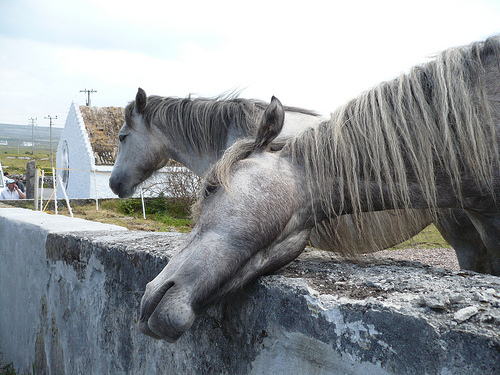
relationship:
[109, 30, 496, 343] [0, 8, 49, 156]
two horses outside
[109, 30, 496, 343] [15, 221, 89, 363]
two horses near a wall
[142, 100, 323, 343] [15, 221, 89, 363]
horse laying head on wall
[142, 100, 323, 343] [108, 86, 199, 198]
head of horse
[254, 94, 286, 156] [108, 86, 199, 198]
ear of horse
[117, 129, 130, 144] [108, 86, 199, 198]
eye of horse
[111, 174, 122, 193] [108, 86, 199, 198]
nose of horse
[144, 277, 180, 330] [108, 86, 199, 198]
mouth of horse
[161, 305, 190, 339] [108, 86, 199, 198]
chin of horse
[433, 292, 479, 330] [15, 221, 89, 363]
chips on wall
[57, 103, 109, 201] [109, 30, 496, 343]
church near horses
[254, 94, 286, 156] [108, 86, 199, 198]
ear of grey horse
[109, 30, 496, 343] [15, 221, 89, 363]
two horses at wall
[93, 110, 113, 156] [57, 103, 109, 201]
brown on building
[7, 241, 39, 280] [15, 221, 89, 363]
grey stone wall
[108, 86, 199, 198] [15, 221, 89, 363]
horse on wall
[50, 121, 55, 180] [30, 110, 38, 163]
wooden electrical pole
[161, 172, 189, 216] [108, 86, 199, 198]
shrubs near horse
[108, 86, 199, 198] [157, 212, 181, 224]
horse in grass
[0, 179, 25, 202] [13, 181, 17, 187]
man on phone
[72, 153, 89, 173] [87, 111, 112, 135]
white house with brown roof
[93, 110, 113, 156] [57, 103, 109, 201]
brown roof on white house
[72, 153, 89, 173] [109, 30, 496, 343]
white house near horses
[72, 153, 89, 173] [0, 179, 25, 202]
white house near man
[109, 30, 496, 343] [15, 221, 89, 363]
two horses near wall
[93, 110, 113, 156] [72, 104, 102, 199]
brown roof on white building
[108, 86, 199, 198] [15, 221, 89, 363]
horse with head on wall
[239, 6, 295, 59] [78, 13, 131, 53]
clouds covering sky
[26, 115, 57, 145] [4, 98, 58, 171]
poles in distance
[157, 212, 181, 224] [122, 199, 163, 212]
grass near bushes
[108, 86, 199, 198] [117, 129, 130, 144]
horse with black eye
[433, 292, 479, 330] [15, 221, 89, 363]
chips on concrete wall